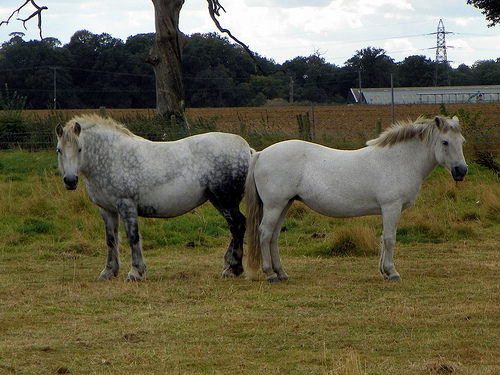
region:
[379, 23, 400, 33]
this is the sky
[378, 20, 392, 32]
the sky is blue in color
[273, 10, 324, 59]
the sky has clouds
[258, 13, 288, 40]
the clouds are white in color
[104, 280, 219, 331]
this is the grass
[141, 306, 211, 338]
the grass is green in color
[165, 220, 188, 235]
the grass is short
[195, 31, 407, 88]
these are some trees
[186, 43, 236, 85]
the leaves are green in color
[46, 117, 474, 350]
these are two horses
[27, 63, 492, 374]
two horses standing in field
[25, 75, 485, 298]
horses are standing back to back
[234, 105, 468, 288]
horse is white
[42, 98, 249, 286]
horse is white and black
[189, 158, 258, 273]
black horse hind legs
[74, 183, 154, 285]
black and white front horse legs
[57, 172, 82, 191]
horse has black nose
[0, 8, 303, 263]
tree with limbs behind horses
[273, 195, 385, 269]
patch of green and brown grass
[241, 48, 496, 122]
long white building in background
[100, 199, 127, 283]
leg of a horse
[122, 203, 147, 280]
leg of a horse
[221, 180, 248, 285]
leg of a horse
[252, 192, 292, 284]
leg of a horse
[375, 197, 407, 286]
leg of a horse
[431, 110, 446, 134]
ear of a horse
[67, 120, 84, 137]
ear of a horse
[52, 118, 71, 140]
ear of a horse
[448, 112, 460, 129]
ear of a horse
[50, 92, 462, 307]
two horses standing in a field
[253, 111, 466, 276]
a white horse standing in a field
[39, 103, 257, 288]
a black and white horse standing in a field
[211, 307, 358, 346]
green grass of the field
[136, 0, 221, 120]
tree growing outside of the fence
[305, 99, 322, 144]
grey metal fence post behind the horses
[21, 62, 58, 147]
grey metal wires of the fence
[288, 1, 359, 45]
cloudy white skies over the field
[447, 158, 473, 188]
black nose and mouth of the white horse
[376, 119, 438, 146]
blone mane of the white horse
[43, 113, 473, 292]
Two horses standing opposite each other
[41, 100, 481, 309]
Two horses unknowingly mirroring stance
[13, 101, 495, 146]
Field of plowed field above horses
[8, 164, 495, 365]
Grass maintained for grazing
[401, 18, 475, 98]
Telephone pole in distance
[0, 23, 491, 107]
Grove of trees on horizon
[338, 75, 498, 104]
Building kept for storage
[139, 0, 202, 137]
Old tree trunk in middle of field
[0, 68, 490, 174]
Small fence to keep horses in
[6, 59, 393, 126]
Telephone wires hanging